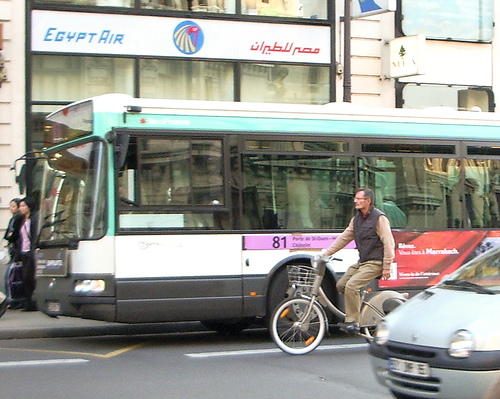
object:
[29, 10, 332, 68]
sign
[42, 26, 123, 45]
egypt air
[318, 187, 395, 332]
man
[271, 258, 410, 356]
bike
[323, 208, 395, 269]
jacket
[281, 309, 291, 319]
reflector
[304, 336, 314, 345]
reflector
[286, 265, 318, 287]
basket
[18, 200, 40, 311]
woman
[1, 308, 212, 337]
sidewalk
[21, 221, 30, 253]
shirt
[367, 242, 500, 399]
car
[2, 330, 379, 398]
street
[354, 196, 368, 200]
glasses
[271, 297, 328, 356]
tire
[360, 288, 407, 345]
tire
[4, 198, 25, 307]
woman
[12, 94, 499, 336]
bus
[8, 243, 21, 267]
black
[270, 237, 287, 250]
number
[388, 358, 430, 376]
license plant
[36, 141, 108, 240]
windshield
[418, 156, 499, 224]
reflection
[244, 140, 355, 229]
window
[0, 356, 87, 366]
line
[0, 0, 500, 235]
building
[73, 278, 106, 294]
headlight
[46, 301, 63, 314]
license plate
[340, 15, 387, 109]
wall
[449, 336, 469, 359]
headlight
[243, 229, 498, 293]
ad